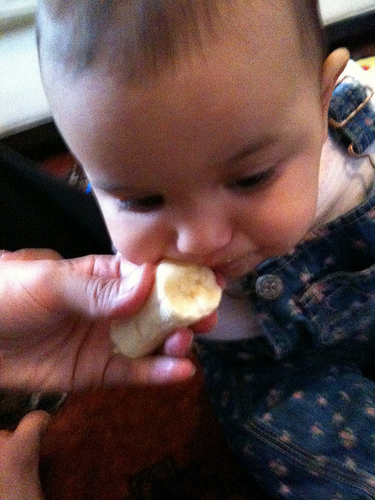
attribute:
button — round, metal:
[257, 275, 281, 300]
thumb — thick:
[40, 259, 153, 319]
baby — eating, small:
[36, 2, 373, 497]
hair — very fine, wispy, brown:
[35, 1, 327, 90]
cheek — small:
[253, 184, 316, 253]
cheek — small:
[103, 209, 170, 266]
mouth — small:
[212, 241, 257, 275]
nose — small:
[176, 189, 234, 253]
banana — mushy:
[111, 257, 221, 360]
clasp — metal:
[207, 261, 285, 302]